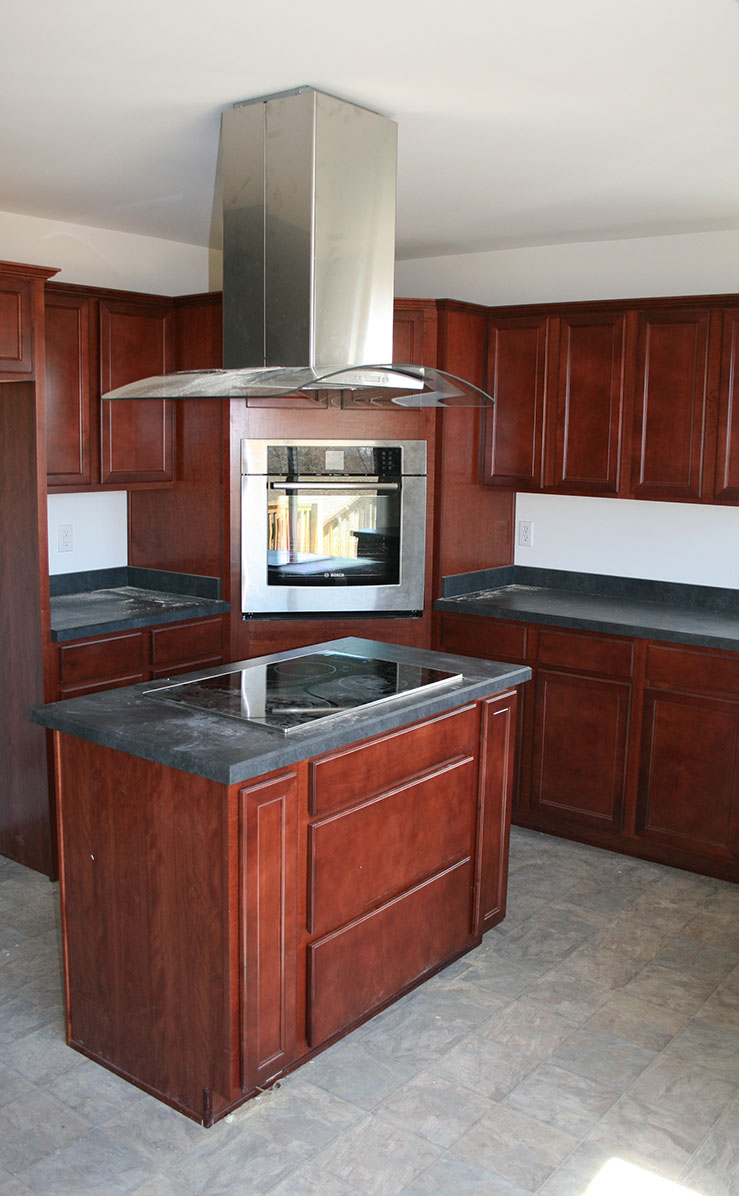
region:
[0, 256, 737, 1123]
the cabinets are wood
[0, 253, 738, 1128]
the cabinets are brown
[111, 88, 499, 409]
the vent is silver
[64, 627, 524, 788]
the counter top is black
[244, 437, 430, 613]
the stove is silver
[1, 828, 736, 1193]
the floor is tiled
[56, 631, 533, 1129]
the island is made of wood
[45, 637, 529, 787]
the counter is dusty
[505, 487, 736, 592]
the wall is white and clean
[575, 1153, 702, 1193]
the light is shining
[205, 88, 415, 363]
pipe that connects hood to ceiling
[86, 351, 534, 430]
Glass range hood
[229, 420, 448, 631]
built in stove in the wall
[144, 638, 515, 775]
counter top electrical stove top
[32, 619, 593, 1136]
kitchen island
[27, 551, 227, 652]
empty counter to the left of the oven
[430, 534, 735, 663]
empty counter to the left of the oven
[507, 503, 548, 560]
outlet next to the oevn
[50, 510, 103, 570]
outlet on the wall with the small counter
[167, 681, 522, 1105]
front part of the island with the doors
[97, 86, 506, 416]
a steel ventilator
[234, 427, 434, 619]
an oven inserted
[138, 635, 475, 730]
a modern stove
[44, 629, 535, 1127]
an island in the kitchen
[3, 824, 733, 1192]
th tiled flooring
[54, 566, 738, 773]
the marbled countertops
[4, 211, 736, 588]
the white walls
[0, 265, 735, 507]
the top cabinets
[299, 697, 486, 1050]
the drawers under the stove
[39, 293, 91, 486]
A door for a cabinet.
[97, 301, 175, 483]
A door for a cabinet.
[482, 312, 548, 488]
A door for a cabinet.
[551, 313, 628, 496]
A door for a cabinet.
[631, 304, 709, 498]
A door for a cabinet.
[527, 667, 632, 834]
A door for a cabinet.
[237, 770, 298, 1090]
A door for a cabinet.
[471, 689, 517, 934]
A door for a cabinet.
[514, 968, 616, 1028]
A tile in a floor.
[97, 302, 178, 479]
cabinet door is brown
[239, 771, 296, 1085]
cabinet door is brown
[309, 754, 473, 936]
cabinet door is brown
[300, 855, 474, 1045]
cabinet door is brown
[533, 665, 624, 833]
cabinet door is brown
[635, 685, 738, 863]
cabinet door is brown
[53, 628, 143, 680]
cabinet door is brown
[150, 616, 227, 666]
cabinet door is brown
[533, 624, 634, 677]
cabinet door is brown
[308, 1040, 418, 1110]
A tile in a floor.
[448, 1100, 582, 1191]
A tile in a floor.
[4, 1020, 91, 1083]
A tile in a floor.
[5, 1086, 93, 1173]
A tile in a floor.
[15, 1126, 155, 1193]
A tile in a floor.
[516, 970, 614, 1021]
A tile in a floor.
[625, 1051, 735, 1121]
A tile in a floor.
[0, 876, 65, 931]
A tile in a floor.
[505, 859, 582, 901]
A tile in a floor.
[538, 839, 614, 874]
A tile in a floor.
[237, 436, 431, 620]
silver and black colored oven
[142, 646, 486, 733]
silver and black range top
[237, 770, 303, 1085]
dark brown colored cabinet in kitchen